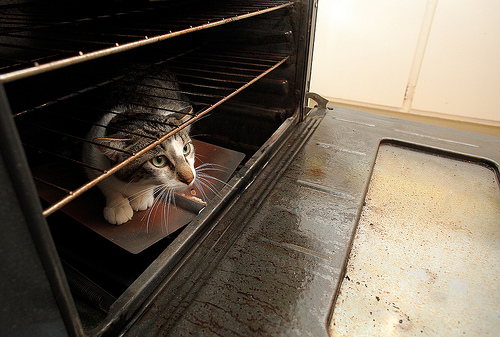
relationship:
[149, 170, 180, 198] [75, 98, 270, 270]
jaw of cat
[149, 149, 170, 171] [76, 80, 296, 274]
eye of cat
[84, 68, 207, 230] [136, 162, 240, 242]
cat has whiskers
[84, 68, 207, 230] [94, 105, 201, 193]
cat has head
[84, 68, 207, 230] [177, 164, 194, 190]
cat has nose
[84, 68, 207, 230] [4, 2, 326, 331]
cat in oven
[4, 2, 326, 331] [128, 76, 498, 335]
oven has door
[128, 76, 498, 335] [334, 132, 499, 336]
door has window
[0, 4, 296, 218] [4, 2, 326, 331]
rack in oven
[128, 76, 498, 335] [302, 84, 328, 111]
door has hinge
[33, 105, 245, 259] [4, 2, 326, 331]
plate in oven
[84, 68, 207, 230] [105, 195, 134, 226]
cat has paw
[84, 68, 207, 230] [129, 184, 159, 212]
cat has paw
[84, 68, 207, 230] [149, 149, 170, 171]
cat has eye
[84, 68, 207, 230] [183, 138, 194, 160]
cat has eye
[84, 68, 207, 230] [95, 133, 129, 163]
cat has ear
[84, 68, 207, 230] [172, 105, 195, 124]
cat has ear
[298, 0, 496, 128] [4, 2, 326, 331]
wall behind oven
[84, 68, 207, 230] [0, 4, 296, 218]
cat under rack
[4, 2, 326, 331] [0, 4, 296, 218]
oven has rack